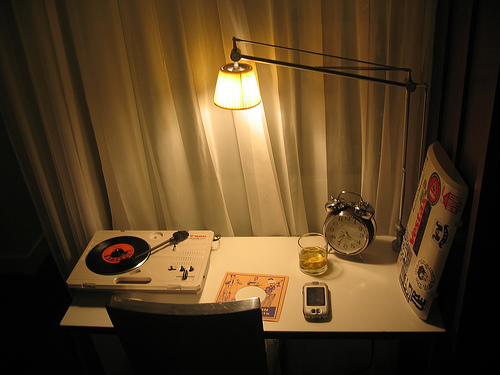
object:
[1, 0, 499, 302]
curtains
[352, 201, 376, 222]
bell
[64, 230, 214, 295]
player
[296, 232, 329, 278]
glass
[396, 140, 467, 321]
oval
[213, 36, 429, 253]
lamp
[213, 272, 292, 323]
cover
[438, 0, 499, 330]
wall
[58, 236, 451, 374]
table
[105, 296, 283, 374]
chair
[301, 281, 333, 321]
device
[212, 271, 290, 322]
record container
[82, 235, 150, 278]
record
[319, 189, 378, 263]
alarm clock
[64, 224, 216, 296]
record/turntable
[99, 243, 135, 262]
red label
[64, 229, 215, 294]
turntable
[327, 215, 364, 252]
face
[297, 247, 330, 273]
drink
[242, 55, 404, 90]
pole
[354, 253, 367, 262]
legs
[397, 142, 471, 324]
pictures